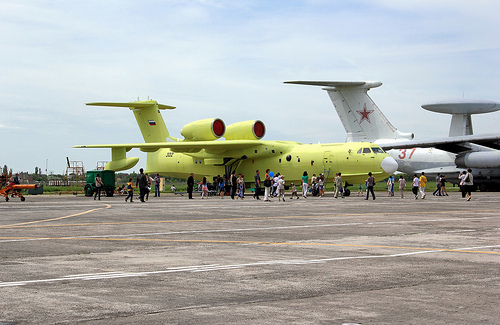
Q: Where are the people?
A: On the tarmac.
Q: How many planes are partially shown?
A: Two.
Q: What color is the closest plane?
A: Yellow.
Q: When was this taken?
A: During the day.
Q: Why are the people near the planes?
A: To look up close.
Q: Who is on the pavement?
A: Passengers.